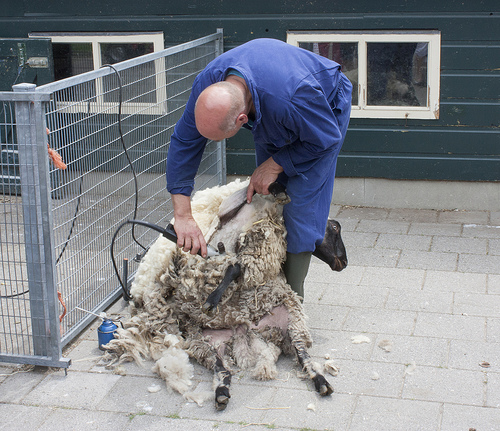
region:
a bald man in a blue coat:
[56, 14, 416, 425]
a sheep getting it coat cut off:
[99, 157, 411, 423]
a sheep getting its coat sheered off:
[82, 163, 401, 418]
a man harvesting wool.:
[35, 34, 429, 409]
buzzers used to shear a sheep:
[86, 159, 359, 397]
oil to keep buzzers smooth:
[71, 215, 258, 367]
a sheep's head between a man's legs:
[113, 200, 381, 390]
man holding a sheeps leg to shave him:
[137, 57, 388, 412]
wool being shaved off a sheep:
[126, 165, 302, 364]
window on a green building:
[283, 14, 465, 159]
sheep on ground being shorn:
[97, 165, 354, 415]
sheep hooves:
[209, 368, 338, 414]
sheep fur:
[246, 233, 277, 260]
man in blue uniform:
[169, 35, 357, 261]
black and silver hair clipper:
[136, 215, 237, 276]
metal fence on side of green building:
[3, 26, 233, 373]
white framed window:
[27, 25, 170, 119]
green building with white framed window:
[1, 0, 495, 207]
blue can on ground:
[68, 300, 121, 358]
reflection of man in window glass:
[341, 44, 400, 101]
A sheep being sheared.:
[98, 179, 335, 411]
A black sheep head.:
[310, 213, 350, 272]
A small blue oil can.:
[69, 304, 116, 351]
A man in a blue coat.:
[165, 37, 355, 307]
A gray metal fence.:
[0, 27, 227, 374]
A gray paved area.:
[0, 203, 499, 429]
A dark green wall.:
[1, 0, 499, 182]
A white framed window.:
[284, 31, 442, 119]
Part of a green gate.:
[0, 39, 57, 90]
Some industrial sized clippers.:
[191, 241, 231, 264]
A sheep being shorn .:
[96, 40, 352, 406]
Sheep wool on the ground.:
[93, 281, 413, 412]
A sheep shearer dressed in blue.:
[163, 35, 353, 305]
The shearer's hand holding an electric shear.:
[157, 211, 207, 261]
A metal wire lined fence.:
[1, 25, 221, 365]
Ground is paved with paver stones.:
[0, 185, 497, 430]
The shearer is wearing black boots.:
[281, 215, 346, 296]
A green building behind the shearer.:
[0, 0, 499, 180]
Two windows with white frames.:
[26, 31, 440, 116]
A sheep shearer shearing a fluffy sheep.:
[105, 38, 352, 409]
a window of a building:
[364, 31, 436, 119]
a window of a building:
[96, 32, 167, 118]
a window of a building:
[52, 33, 99, 110]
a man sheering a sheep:
[99, 44, 361, 418]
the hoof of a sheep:
[306, 375, 346, 398]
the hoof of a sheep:
[206, 380, 243, 417]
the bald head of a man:
[183, 75, 254, 150]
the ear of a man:
[230, 108, 255, 133]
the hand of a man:
[170, 210, 207, 260]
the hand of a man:
[235, 160, 275, 205]